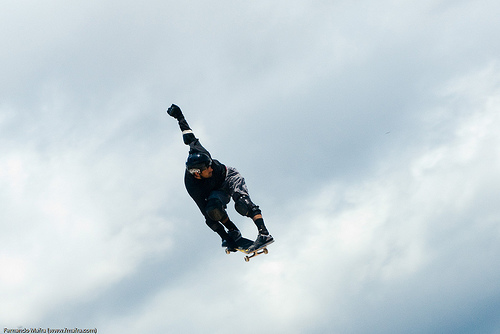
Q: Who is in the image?
A: Person.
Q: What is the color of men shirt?
A: Black.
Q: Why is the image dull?
A: No focus.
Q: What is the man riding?
A: Skateboard.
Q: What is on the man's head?
A: Helmet.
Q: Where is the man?
A: In the air.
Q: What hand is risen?
A: His left.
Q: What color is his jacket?
A: Black.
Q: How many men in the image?
A: One.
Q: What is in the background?
A: Clouds.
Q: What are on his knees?
A: Knee pads.